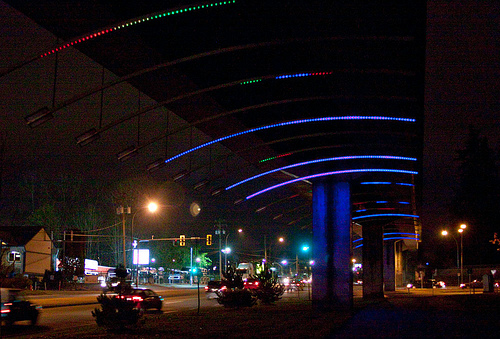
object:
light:
[164, 116, 417, 165]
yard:
[369, 251, 500, 302]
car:
[205, 279, 236, 300]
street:
[40, 300, 89, 339]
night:
[48, 148, 114, 173]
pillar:
[309, 179, 352, 304]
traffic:
[102, 266, 158, 318]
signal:
[302, 246, 310, 251]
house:
[0, 224, 64, 292]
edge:
[42, 225, 59, 248]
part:
[424, 287, 452, 295]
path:
[399, 287, 460, 332]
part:
[384, 147, 405, 165]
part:
[14, 233, 55, 272]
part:
[326, 199, 346, 235]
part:
[182, 251, 189, 262]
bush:
[165, 246, 187, 267]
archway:
[0, 0, 431, 245]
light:
[196, 258, 201, 263]